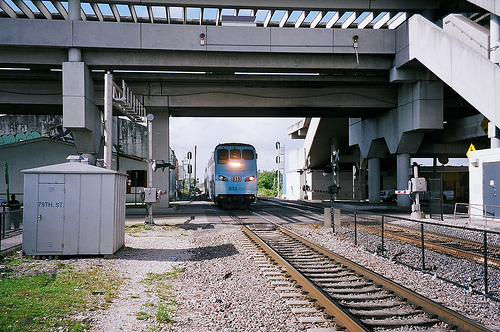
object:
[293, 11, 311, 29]
beam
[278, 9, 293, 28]
beam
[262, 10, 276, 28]
beam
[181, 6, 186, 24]
beam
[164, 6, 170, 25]
beam